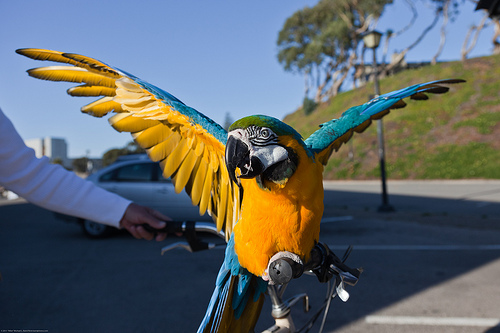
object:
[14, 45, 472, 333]
parrot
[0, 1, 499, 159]
sky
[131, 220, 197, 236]
handle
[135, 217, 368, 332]
bicycle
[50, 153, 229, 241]
vehicle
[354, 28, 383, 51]
lamp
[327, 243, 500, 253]
stripe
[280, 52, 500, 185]
hill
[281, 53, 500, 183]
grass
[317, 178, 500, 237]
sidewalk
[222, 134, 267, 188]
beak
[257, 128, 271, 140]
eye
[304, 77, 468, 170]
wing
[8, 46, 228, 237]
wing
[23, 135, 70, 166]
building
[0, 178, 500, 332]
parking lot